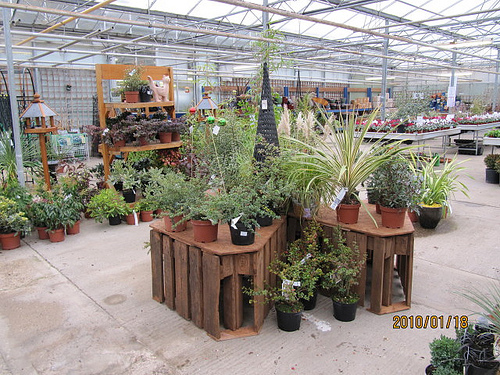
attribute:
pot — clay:
[209, 194, 278, 283]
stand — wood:
[113, 218, 322, 372]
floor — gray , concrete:
[33, 152, 463, 359]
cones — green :
[244, 48, 298, 191]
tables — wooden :
[129, 160, 479, 373]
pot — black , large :
[414, 171, 454, 251]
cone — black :
[234, 46, 326, 249]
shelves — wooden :
[94, 62, 207, 232]